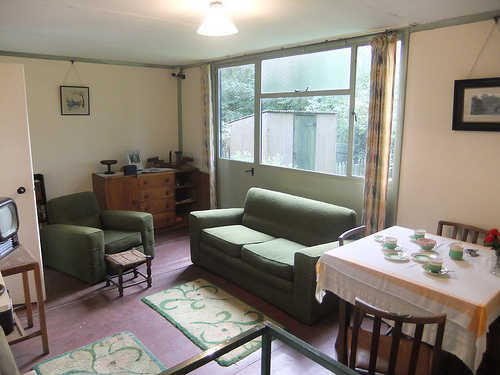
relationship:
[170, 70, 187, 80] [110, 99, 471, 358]
security camera in room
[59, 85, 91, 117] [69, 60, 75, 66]
picture hanging on a hook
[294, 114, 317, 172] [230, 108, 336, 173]
door on shed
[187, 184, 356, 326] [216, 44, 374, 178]
sofa by window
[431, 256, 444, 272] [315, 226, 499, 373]
tea cup on table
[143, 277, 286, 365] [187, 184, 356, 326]
rug in front of sofa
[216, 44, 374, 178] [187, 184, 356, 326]
window behind sofa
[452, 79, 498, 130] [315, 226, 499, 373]
picture on wall behind table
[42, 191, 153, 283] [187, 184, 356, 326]
chair matches sofa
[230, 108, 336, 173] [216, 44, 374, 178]
shed seen through window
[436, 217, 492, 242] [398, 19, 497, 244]
chair against wall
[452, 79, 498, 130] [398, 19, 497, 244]
picture hanging on wall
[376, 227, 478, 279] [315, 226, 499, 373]
cups and saucers on a table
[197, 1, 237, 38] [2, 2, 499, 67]
light fixture on ceiling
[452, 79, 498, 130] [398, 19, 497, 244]
picture on wall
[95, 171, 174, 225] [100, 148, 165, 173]
dresser topped with knicknacks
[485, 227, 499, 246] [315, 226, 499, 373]
rose on table